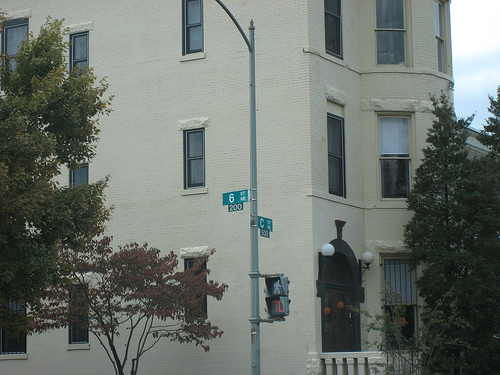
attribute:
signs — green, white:
[213, 183, 248, 213]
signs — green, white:
[253, 210, 277, 239]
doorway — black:
[312, 238, 372, 354]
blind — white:
[372, 110, 416, 160]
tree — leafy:
[368, 65, 491, 371]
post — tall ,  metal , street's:
[243, 22, 265, 373]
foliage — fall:
[26, 245, 228, 352]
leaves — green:
[401, 90, 498, 369]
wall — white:
[133, 70, 196, 126]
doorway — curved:
[317, 240, 364, 353]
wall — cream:
[166, 86, 357, 280]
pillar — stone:
[318, 357, 325, 374]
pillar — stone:
[327, 352, 339, 373]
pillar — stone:
[340, 353, 348, 373]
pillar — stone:
[349, 352, 360, 374]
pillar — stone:
[360, 351, 370, 373]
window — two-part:
[170, 115, 227, 207]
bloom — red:
[200, 344, 212, 354]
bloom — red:
[217, 281, 227, 293]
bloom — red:
[130, 241, 142, 249]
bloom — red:
[112, 329, 119, 336]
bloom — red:
[42, 322, 54, 330]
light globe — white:
[319, 242, 336, 257]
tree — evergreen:
[10, 139, 86, 267]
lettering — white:
[224, 190, 255, 207]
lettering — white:
[257, 216, 272, 231]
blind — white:
[364, 102, 422, 217]